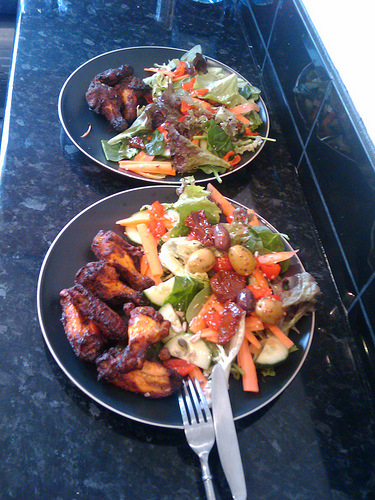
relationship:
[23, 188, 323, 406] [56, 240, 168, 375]
plate with chicken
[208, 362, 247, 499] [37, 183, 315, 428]
knife on plate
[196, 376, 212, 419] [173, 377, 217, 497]
tine om silver fork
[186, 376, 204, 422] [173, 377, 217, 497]
tine om silver fork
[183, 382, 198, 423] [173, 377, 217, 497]
tine om silver fork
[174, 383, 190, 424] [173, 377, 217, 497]
tine om silver fork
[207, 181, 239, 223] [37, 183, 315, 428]
carrot on plate